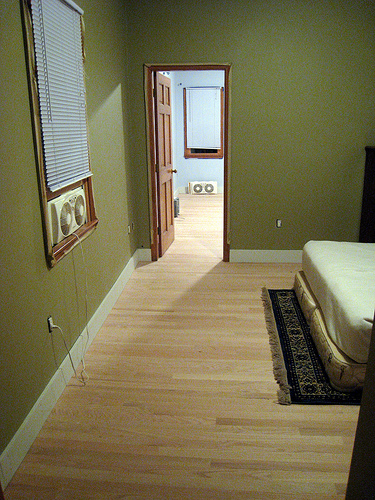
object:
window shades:
[32, 2, 96, 192]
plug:
[46, 316, 55, 334]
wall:
[125, 0, 374, 266]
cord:
[52, 234, 90, 386]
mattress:
[302, 237, 372, 361]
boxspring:
[290, 270, 368, 392]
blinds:
[31, 0, 92, 194]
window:
[183, 88, 221, 155]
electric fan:
[73, 191, 89, 228]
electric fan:
[60, 204, 76, 235]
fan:
[180, 177, 218, 198]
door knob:
[170, 167, 176, 174]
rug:
[259, 287, 360, 406]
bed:
[293, 234, 373, 394]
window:
[30, 2, 96, 196]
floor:
[13, 196, 366, 498]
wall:
[0, 0, 137, 452]